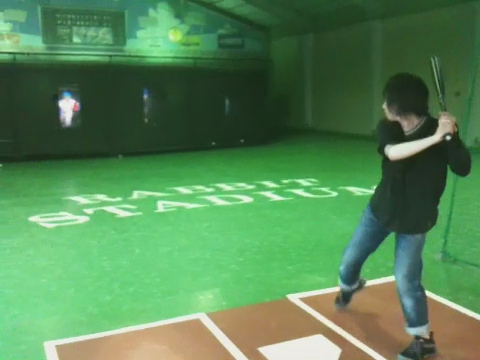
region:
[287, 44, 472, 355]
person standing in the white box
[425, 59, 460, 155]
both hands on the bat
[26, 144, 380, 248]
white writing on the ground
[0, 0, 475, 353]
batting cages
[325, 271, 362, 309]
heel is lifted of the ground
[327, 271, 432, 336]
pants are rolled up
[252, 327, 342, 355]
white homeplate painted on the ground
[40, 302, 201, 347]
white line on the ground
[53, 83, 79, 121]
picture of a pitcher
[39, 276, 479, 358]
brown dirt painted on the ground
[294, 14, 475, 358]
an indoor batting cage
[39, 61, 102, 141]
a video pitcher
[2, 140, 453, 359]
a linoleum floor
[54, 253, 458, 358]
this section of the floor is made to look like home plate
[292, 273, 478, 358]
he is standing in the batters box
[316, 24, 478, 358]
this guy has long hair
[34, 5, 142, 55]
a scoreboard painted on the wall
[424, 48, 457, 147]
a black baseball bat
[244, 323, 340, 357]
home plate is white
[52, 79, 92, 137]
the pitcher is lit up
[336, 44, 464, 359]
a man holding a bat.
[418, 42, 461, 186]
a small baseball bat.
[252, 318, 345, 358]
a white baseball base.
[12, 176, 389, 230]
writing on astroturf.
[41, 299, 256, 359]
a white square on a baseball field.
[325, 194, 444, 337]
a pair of blue jeans.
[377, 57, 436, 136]
a helmet on a head.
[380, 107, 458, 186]
an arm on a man.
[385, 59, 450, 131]
a dark baseball helmet.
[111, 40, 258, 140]
a dark green wall.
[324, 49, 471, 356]
Boy Holding Baseball Bat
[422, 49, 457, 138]
Baseball Bat in Batter's Hands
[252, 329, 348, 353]
Baseball Diamond in Stadium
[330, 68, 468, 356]
Young Boy Standing Up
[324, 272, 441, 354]
Pair of Tennis Shoes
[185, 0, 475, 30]
This is the Ceiling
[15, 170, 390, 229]
Text That Reads Rabbit Stadium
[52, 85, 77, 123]
Pitching machine throwing ball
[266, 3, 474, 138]
This is the wall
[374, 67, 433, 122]
Black Hair On Boy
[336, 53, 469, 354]
Boy holding a baseball bat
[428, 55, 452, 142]
The bat is black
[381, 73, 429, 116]
Boy has long hair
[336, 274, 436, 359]
The shoes are black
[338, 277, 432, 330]
Pant cuffs rolled up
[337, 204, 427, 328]
The pants are blue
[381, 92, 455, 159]
Boy has pale skin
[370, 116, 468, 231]
The shirt is black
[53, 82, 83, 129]
Image of a baseball pitcher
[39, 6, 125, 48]
Green sign on wall